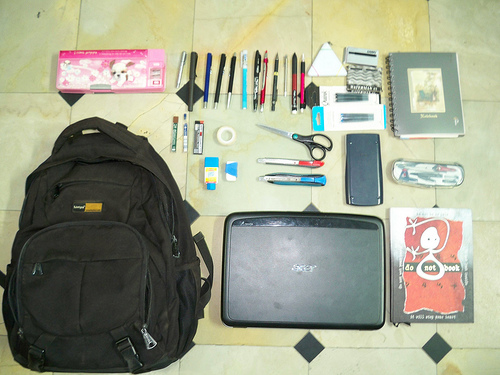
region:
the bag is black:
[17, 99, 191, 373]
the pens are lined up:
[148, 41, 350, 122]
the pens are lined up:
[157, 34, 429, 165]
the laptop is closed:
[212, 214, 387, 341]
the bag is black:
[33, 132, 207, 374]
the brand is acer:
[221, 214, 398, 329]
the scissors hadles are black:
[271, 120, 332, 163]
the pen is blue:
[232, 67, 252, 105]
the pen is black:
[215, 53, 227, 109]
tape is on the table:
[213, 119, 242, 149]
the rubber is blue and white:
[220, 152, 242, 187]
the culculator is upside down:
[344, 136, 391, 206]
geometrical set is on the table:
[387, 155, 482, 192]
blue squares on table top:
[282, 331, 331, 358]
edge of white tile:
[338, 338, 393, 362]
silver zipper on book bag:
[139, 320, 164, 354]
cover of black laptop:
[218, 200, 388, 340]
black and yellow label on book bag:
[61, 198, 116, 219]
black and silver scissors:
[254, 119, 353, 158]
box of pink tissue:
[40, 32, 198, 100]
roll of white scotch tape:
[207, 121, 246, 151]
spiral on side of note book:
[383, 45, 404, 149]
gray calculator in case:
[335, 130, 395, 202]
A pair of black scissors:
[250, 112, 335, 162]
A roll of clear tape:
[210, 120, 240, 145]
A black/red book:
[380, 195, 475, 325]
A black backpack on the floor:
[0, 115, 215, 370]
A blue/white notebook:
[385, 35, 470, 140]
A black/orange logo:
[67, 195, 102, 215]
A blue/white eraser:
[220, 155, 241, 181]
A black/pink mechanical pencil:
[292, 55, 307, 115]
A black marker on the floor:
[246, 45, 258, 111]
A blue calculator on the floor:
[335, 130, 386, 211]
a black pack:
[0, 114, 205, 371]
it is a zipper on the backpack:
[140, 326, 162, 352]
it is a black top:
[224, 213, 389, 330]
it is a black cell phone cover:
[345, 132, 384, 207]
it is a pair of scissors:
[256, 125, 334, 159]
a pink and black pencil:
[296, 54, 308, 110]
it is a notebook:
[386, 52, 471, 141]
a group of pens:
[181, 43, 287, 108]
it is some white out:
[200, 150, 224, 190]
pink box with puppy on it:
[53, 44, 172, 100]